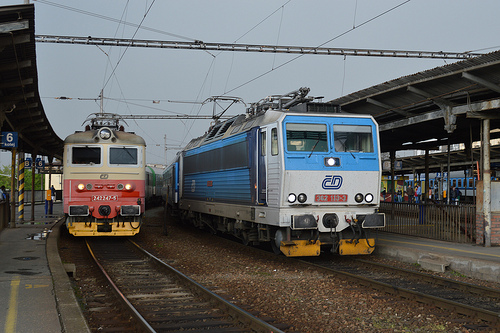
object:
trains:
[83, 98, 377, 245]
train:
[62, 120, 149, 240]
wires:
[56, 14, 344, 116]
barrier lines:
[3, 276, 21, 333]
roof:
[0, 3, 64, 161]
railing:
[379, 199, 476, 245]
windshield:
[282, 120, 369, 157]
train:
[161, 101, 386, 257]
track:
[96, 264, 285, 333]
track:
[319, 263, 499, 319]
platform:
[0, 123, 63, 283]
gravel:
[265, 281, 361, 319]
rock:
[278, 287, 365, 325]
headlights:
[297, 193, 307, 204]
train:
[195, 118, 361, 237]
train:
[166, 118, 403, 270]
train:
[31, 115, 137, 239]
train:
[70, 220, 166, 271]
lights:
[326, 157, 336, 166]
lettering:
[321, 175, 342, 190]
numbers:
[91, 195, 119, 201]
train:
[393, 167, 485, 214]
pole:
[17, 151, 24, 225]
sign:
[0, 133, 18, 147]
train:
[62, 129, 145, 237]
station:
[0, 3, 499, 333]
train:
[159, 94, 379, 264]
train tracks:
[81, 229, 268, 330]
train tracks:
[77, 236, 284, 330]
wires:
[35, 4, 498, 98]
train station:
[1, 2, 488, 331]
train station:
[26, 31, 498, 76]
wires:
[35, 22, 498, 67]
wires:
[55, 94, 251, 124]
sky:
[0, 0, 500, 174]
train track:
[81, 238, 275, 330]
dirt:
[105, 271, 500, 333]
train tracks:
[68, 191, 498, 331]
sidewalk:
[0, 193, 62, 333]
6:
[7, 132, 14, 142]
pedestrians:
[379, 185, 460, 206]